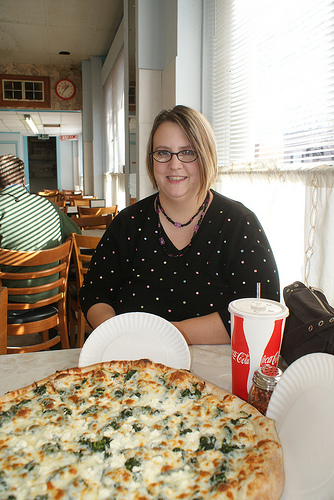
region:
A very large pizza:
[3, 357, 278, 494]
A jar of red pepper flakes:
[245, 363, 282, 406]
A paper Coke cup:
[216, 298, 268, 383]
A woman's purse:
[275, 279, 332, 353]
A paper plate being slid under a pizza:
[78, 308, 192, 368]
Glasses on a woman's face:
[143, 139, 222, 193]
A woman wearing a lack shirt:
[76, 183, 263, 312]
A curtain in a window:
[230, 158, 330, 247]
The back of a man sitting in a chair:
[7, 166, 71, 319]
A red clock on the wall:
[49, 77, 77, 110]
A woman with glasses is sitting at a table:
[86, 20, 286, 361]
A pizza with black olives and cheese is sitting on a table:
[1, 362, 301, 498]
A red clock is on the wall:
[47, 72, 73, 97]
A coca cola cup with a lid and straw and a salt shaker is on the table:
[226, 281, 289, 407]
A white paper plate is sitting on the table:
[85, 306, 193, 364]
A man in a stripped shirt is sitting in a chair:
[2, 154, 73, 347]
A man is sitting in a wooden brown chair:
[0, 153, 75, 351]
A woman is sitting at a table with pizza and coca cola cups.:
[3, 10, 281, 494]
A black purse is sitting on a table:
[285, 273, 333, 362]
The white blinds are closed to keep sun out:
[203, 0, 332, 111]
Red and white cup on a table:
[216, 280, 304, 401]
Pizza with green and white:
[11, 370, 232, 498]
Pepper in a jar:
[248, 362, 290, 411]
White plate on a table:
[73, 294, 203, 385]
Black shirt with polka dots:
[94, 180, 270, 330]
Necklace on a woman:
[139, 97, 230, 230]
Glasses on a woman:
[151, 140, 207, 176]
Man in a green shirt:
[2, 152, 72, 267]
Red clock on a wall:
[50, 75, 82, 102]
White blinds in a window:
[193, 85, 332, 159]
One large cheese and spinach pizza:
[3, 363, 276, 498]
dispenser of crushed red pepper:
[245, 358, 282, 409]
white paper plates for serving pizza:
[281, 329, 333, 492]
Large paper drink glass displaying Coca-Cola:
[220, 265, 285, 378]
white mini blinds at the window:
[245, 54, 332, 164]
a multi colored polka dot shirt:
[76, 203, 287, 310]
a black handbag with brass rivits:
[276, 239, 333, 349]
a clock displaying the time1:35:
[50, 71, 82, 107]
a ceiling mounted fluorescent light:
[15, 113, 46, 144]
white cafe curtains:
[216, 153, 333, 288]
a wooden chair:
[71, 225, 123, 337]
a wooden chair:
[1, 239, 79, 344]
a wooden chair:
[68, 208, 109, 233]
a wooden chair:
[73, 199, 120, 224]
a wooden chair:
[59, 202, 74, 214]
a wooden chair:
[69, 193, 103, 206]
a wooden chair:
[45, 191, 65, 201]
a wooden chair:
[46, 184, 62, 194]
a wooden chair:
[63, 187, 76, 196]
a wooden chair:
[68, 189, 85, 198]